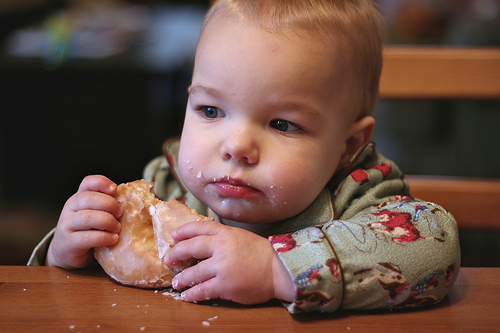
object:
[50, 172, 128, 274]
hand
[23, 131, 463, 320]
pajamas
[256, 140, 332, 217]
cheek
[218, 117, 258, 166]
nose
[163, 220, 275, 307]
hand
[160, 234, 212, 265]
finger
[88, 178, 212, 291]
donut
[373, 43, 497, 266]
chair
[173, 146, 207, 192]
cheek part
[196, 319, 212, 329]
crumbs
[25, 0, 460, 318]
baby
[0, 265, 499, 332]
table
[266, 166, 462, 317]
sleeve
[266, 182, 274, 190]
icing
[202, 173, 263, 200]
mouth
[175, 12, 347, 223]
face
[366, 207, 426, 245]
pattern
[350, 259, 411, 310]
pattern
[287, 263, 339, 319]
pattern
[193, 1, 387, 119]
hair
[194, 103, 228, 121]
eye